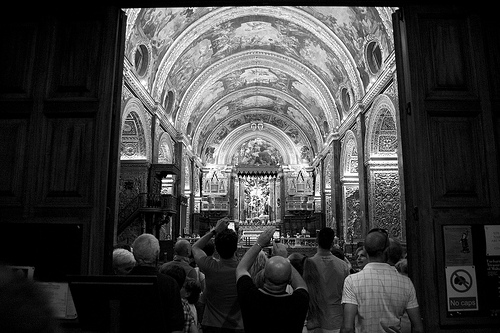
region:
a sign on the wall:
[446, 266, 481, 311]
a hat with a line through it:
[451, 269, 472, 291]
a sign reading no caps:
[451, 295, 478, 310]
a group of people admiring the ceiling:
[115, 216, 422, 331]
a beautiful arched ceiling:
[126, 0, 379, 167]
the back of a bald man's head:
[262, 255, 295, 291]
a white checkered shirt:
[346, 265, 419, 332]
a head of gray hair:
[131, 232, 158, 262]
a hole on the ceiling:
[132, 44, 149, 72]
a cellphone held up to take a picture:
[271, 225, 283, 246]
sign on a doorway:
[443, 219, 477, 317]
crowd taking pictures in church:
[109, 206, 406, 323]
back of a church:
[230, 164, 285, 233]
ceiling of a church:
[164, 6, 361, 149]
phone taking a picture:
[263, 224, 286, 250]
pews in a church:
[283, 234, 319, 254]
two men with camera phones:
[196, 220, 319, 331]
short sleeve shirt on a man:
[341, 255, 421, 328]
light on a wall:
[159, 166, 176, 205]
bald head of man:
[263, 255, 290, 282]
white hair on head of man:
[141, 230, 161, 265]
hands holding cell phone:
[265, 225, 282, 256]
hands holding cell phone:
[226, 216, 239, 227]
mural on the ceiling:
[132, 0, 387, 173]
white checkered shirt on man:
[340, 260, 412, 326]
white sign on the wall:
[443, 265, 488, 310]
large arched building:
[115, 0, 392, 162]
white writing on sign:
[446, 295, 478, 307]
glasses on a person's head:
[338, 223, 406, 271]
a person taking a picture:
[231, 224, 311, 328]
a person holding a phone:
[187, 209, 243, 312]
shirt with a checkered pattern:
[343, 267, 420, 332]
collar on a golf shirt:
[356, 257, 406, 286]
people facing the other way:
[109, 224, 347, 317]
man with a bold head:
[261, 256, 296, 296]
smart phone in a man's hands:
[258, 222, 285, 246]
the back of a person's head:
[191, 210, 248, 267]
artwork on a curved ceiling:
[156, 14, 353, 172]